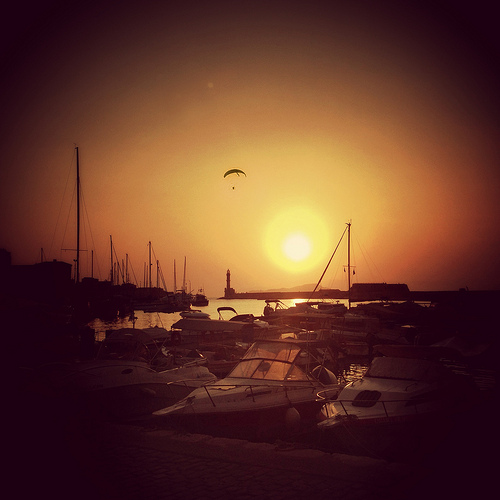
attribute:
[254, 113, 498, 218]
sky — orange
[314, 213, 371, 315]
silhouette — black mast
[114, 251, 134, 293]
silhouette — black mast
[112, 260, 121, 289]
silhouette — black mast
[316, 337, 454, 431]
boat — white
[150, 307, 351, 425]
boat — white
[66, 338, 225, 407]
boat — white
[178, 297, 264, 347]
boat — white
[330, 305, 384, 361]
boat — white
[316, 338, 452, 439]
boat — white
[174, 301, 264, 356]
boat — white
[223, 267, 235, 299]
building — tall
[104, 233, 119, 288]
mast — black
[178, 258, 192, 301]
mast — black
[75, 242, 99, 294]
mast — black